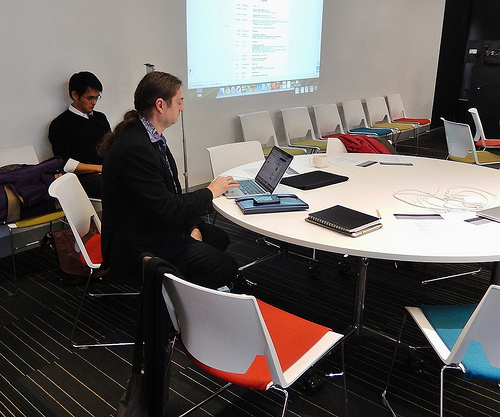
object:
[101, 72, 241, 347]
man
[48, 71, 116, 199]
man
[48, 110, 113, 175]
sweater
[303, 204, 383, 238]
notebooks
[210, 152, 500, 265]
table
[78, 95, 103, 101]
glasses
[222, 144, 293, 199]
laptop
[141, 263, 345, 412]
chair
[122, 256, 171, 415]
bag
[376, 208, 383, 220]
pencil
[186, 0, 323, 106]
projection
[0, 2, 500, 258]
wall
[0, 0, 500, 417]
room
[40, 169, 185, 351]
chairs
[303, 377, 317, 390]
wheels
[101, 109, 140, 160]
pony tail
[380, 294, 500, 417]
seat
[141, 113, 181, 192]
shirt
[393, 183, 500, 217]
cable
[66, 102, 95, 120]
shirt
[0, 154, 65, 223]
bag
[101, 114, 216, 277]
jacket